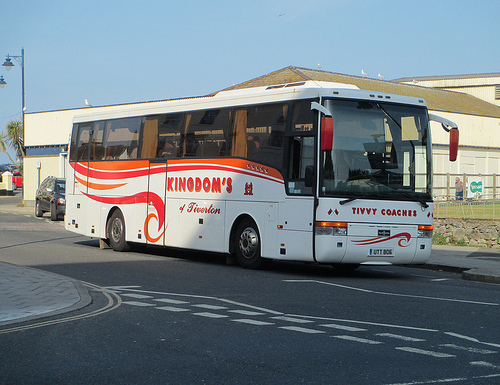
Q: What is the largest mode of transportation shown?
A: Bus.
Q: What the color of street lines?
A: White.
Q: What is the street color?
A: Grey.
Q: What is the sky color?
A: Blue.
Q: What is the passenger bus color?
A: White and red.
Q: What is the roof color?
A: Brown.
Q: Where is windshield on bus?
A: Front.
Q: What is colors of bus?
A: White and red.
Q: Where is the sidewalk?
A: Corner.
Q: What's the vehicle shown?
A: Bus.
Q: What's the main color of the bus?
A: White.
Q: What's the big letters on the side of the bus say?
A: KINGDOM'S.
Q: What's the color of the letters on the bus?
A: Red.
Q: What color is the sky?
A: Blue.